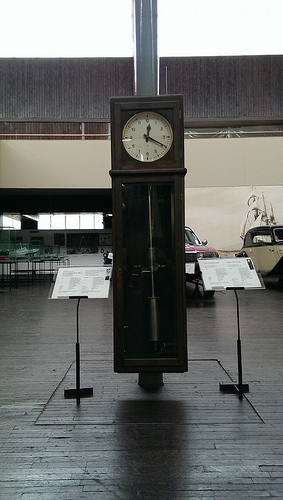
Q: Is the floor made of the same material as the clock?
A: Yes, both the floor and the clock are made of wood.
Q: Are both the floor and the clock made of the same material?
A: Yes, both the floor and the clock are made of wood.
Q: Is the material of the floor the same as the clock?
A: Yes, both the floor and the clock are made of wood.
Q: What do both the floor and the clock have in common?
A: The material, both the floor and the clock are wooden.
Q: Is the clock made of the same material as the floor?
A: Yes, both the clock and the floor are made of wood.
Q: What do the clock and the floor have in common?
A: The material, both the clock and the floor are wooden.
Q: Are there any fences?
A: No, there are no fences.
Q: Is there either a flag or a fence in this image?
A: No, there are no fences or flags.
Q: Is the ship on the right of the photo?
A: Yes, the ship is on the right of the image.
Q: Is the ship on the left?
A: No, the ship is on the right of the image.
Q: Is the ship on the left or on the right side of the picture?
A: The ship is on the right of the image.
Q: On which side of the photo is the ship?
A: The ship is on the right of the image.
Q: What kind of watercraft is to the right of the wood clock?
A: The watercraft is a ship.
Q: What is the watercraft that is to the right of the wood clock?
A: The watercraft is a ship.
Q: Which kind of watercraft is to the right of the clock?
A: The watercraft is a ship.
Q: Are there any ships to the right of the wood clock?
A: Yes, there is a ship to the right of the clock.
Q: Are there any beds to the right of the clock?
A: No, there is a ship to the right of the clock.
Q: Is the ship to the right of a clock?
A: Yes, the ship is to the right of a clock.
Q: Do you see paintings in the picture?
A: No, there are no paintings.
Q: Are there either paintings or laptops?
A: No, there are no paintings or laptops.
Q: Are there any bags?
A: No, there are no bags.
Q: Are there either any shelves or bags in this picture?
A: No, there are no bags or shelves.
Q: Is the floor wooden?
A: Yes, the floor is wooden.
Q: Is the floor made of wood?
A: Yes, the floor is made of wood.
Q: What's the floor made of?
A: The floor is made of wood.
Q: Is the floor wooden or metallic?
A: The floor is wooden.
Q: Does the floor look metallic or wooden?
A: The floor is wooden.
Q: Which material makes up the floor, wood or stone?
A: The floor is made of wood.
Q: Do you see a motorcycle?
A: No, there are no motorcycles.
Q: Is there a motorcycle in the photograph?
A: No, there are no motorcycles.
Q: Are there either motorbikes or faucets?
A: No, there are no motorbikes or faucets.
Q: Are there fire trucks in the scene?
A: No, there are no fire trucks.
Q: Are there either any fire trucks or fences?
A: No, there are no fire trucks or fences.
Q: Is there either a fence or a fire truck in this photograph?
A: No, there are no fire trucks or fences.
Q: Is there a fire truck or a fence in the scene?
A: No, there are no fire trucks or fences.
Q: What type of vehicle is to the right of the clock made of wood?
A: The vehicle is a car.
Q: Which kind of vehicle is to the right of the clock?
A: The vehicle is a car.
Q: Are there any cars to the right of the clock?
A: Yes, there is a car to the right of the clock.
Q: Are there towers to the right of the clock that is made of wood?
A: No, there is a car to the right of the clock.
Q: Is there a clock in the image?
A: Yes, there is a clock.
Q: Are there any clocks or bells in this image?
A: Yes, there is a clock.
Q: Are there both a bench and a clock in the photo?
A: No, there is a clock but no benches.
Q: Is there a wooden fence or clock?
A: Yes, there is a wood clock.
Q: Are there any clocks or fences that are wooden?
A: Yes, the clock is wooden.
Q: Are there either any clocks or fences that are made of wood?
A: Yes, the clock is made of wood.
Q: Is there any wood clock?
A: Yes, there is a wood clock.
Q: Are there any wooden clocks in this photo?
A: Yes, there is a wood clock.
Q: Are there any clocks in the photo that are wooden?
A: Yes, there is a clock that is wooden.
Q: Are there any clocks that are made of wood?
A: Yes, there is a clock that is made of wood.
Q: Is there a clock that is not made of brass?
A: Yes, there is a clock that is made of wood.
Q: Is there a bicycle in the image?
A: No, there are no bicycles.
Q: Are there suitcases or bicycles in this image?
A: No, there are no bicycles or suitcases.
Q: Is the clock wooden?
A: Yes, the clock is wooden.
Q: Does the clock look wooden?
A: Yes, the clock is wooden.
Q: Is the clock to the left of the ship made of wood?
A: Yes, the clock is made of wood.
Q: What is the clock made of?
A: The clock is made of wood.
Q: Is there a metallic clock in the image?
A: No, there is a clock but it is wooden.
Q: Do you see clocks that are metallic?
A: No, there is a clock but it is wooden.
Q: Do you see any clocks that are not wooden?
A: No, there is a clock but it is wooden.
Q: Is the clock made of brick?
A: No, the clock is made of wood.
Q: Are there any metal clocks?
A: No, there is a clock but it is made of wood.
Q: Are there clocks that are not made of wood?
A: No, there is a clock but it is made of wood.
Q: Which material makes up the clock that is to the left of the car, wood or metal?
A: The clock is made of wood.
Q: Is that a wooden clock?
A: Yes, that is a wooden clock.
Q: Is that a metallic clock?
A: No, that is a wooden clock.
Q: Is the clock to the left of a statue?
A: No, the clock is to the left of the car.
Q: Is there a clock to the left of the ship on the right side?
A: Yes, there is a clock to the left of the ship.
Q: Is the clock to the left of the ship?
A: Yes, the clock is to the left of the ship.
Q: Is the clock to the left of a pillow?
A: No, the clock is to the left of the ship.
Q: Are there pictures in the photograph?
A: No, there are no pictures.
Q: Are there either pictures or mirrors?
A: No, there are no pictures or mirrors.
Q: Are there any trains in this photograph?
A: No, there are no trains.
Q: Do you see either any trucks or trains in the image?
A: No, there are no trains or trucks.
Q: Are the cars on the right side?
A: Yes, the cars are on the right of the image.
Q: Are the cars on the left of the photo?
A: No, the cars are on the right of the image.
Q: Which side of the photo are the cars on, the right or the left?
A: The cars are on the right of the image.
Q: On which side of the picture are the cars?
A: The cars are on the right of the image.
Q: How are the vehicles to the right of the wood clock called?
A: The vehicles are cars.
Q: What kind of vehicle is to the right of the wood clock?
A: The vehicles are cars.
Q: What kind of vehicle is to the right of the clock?
A: The vehicles are cars.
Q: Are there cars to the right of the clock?
A: Yes, there are cars to the right of the clock.